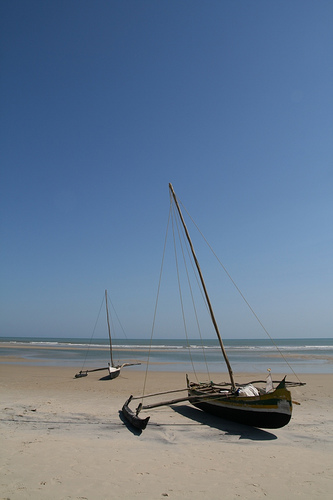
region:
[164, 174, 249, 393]
Tall wooden mast on a boat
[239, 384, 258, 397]
White cloth in a boat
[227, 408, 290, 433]
Dark brown under side of a boat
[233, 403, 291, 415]
White stripe on a boat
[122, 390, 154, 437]
Balancing floater on a boat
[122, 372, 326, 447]
Boat in the sand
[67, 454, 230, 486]
Sand on a beach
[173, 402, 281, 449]
Boat shadow in the sand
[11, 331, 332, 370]
Ocean behind two boats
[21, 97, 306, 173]
Blue sky above two boats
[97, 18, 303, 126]
clear blue cloudless sky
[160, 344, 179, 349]
white foam on wave top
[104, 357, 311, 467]
brown boat sitting on beach sand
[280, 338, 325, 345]
blue calm surface of water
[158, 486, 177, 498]
small rock laying on beach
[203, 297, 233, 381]
wooden sail support pole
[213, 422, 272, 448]
shadow of boat on sand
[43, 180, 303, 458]
two wooden boats on sand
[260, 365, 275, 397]
small white flag in boat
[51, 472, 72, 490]
small track in sand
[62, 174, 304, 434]
two boats docked on sand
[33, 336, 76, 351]
white wave of ocean water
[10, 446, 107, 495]
patch of light tan sand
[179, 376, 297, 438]
green and yellow stripes on side of boat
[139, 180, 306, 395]
sail lines attached to boat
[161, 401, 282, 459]
shadow of boat reflected on tan sand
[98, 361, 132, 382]
white and brown boat on beach sand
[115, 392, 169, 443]
wooden anchor attachment next to wooden boat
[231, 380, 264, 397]
white material inside of boat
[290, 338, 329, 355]
blue and white ocean water in horizon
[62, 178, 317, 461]
two boats grounded on a beach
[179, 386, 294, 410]
two yellow stripes on ship's hull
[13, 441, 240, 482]
white, sandy beach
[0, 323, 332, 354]
flat, distant horizon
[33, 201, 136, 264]
cloudless blue sky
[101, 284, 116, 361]
tall, skinny mast on a boat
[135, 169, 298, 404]
long ropes connected to the top of the mast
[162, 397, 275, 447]
boat's shadow on the beach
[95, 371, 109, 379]
boat's shadow on the beach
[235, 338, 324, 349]
blue ocean water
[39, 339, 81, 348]
waves with white caps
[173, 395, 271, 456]
shadow made by boat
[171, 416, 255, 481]
sand around boat on beach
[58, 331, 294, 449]
two boats on beach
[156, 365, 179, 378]
where the water and sand meet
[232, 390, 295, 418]
stripes on side of boat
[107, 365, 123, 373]
white paint on boat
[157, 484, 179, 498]
hole in the sand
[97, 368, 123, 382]
shadow made by black and white boat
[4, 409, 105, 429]
shadow made by pole of boat